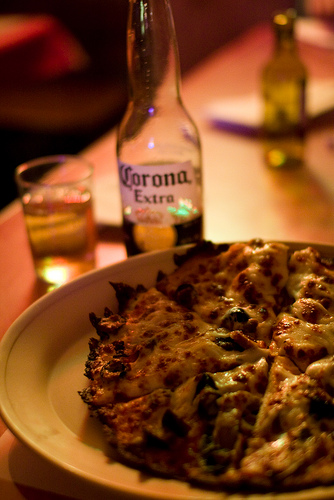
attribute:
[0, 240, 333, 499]
plate — white, round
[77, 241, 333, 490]
pizza — small, sliced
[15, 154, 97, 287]
cup — glass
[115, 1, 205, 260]
bottle — glass, curved, beer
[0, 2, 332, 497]
counter — light brown, long, beige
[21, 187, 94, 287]
drink — tan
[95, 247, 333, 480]
cheese — white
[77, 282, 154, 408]
crust — burnt, well done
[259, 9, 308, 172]
bottle — green, glass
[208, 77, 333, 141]
object — purple, white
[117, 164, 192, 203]
writing — brand